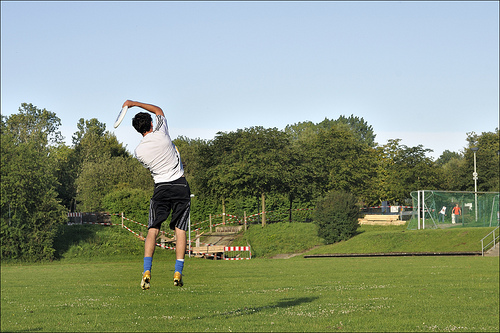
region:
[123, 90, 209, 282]
this is a boy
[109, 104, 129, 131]
this is a frisbee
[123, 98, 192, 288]
the boy is on air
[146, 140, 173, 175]
the t shirt is white in color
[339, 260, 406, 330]
this is the grass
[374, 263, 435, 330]
the grass is green in color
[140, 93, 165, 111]
this is the hand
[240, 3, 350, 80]
this is the sky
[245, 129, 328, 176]
these are the trees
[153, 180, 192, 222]
the short is black in color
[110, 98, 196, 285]
A man jumping in the air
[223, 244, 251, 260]
A white and orange striped barracade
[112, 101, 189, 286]
A man with a frisbee in his hand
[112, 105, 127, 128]
A small white Frisbee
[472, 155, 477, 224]
A small thin white pole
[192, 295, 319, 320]
Shadow of a man on a field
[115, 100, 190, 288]
A man jumping up in the air catching a Frisbee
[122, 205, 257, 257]
A large taped off area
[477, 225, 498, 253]
A small section of metal railing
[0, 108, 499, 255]
A thick row of green trees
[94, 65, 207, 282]
a man on the air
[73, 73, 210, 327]
he has a frissbee on his hand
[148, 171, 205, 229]
his short is black in colour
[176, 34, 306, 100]
the sky is blue in colour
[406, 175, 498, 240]
the net is green in colour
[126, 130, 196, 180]
the shirt is white in colour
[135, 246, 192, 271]
his socks are blue in colour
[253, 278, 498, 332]
the grass is green in colour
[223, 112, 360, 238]
the trees are green in colour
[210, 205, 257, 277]
the ribbons are red and white in colour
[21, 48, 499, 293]
a man flying a frisbee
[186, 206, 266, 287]
a bridge area in the background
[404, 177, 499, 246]
a green net in the distance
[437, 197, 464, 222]
these people are far away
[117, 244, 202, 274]
he is wearing blue socks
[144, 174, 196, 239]
his shorts are black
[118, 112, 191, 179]
his shirt is white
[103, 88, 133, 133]
the frisbee is white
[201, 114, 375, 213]
trees in the area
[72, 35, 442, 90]
clear skies for frisbee flying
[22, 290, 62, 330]
Patch of green grass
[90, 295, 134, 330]
Patch of green grass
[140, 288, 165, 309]
Patch of green grass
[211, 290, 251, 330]
Patch of green grass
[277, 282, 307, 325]
Patch of green grass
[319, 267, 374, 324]
Patch of green grass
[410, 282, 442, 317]
Patch of green grass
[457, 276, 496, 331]
Patch of green grass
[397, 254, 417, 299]
Patch of green grass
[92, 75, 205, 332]
Man in the air